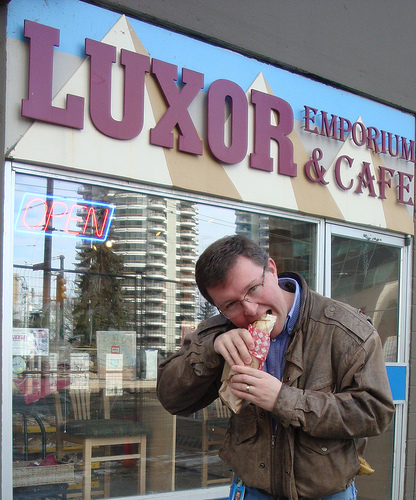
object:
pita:
[218, 314, 278, 414]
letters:
[21, 18, 85, 130]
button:
[329, 305, 335, 311]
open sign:
[14, 191, 115, 244]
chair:
[47, 372, 149, 500]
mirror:
[11, 173, 317, 500]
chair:
[177, 390, 234, 488]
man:
[156, 234, 395, 500]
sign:
[0, 0, 414, 241]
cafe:
[335, 155, 414, 206]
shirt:
[258, 277, 301, 384]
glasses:
[217, 265, 266, 321]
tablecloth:
[13, 377, 72, 406]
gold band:
[246, 384, 250, 393]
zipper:
[269, 414, 279, 500]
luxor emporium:
[19, 18, 414, 177]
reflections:
[70, 174, 199, 358]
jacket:
[156, 273, 395, 500]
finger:
[231, 383, 255, 396]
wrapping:
[246, 323, 271, 371]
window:
[0, 159, 321, 500]